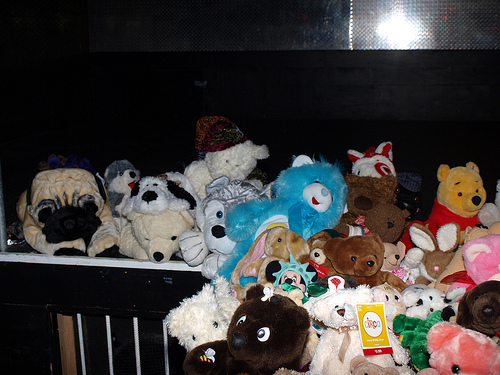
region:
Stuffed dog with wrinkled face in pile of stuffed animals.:
[15, 165, 116, 253]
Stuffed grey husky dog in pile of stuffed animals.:
[95, 156, 140, 211]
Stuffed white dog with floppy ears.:
[120, 170, 200, 215]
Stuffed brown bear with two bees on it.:
[182, 282, 308, 372]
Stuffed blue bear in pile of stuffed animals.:
[213, 153, 348, 285]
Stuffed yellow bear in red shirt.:
[425, 161, 487, 246]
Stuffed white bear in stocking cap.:
[182, 113, 267, 196]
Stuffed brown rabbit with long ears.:
[230, 225, 306, 300]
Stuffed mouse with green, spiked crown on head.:
[265, 250, 315, 285]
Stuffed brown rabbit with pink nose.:
[409, 223, 459, 286]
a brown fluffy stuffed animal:
[325, 233, 403, 290]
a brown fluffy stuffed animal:
[181, 282, 320, 370]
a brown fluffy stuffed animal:
[344, 171, 396, 215]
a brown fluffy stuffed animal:
[337, 200, 407, 245]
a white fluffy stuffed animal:
[164, 285, 238, 348]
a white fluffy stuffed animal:
[304, 285, 404, 373]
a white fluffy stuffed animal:
[374, 281, 414, 365]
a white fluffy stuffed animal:
[400, 282, 463, 320]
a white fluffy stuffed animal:
[177, 137, 267, 191]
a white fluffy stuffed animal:
[117, 206, 201, 265]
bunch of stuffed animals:
[26, 144, 490, 345]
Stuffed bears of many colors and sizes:
[298, 169, 455, 354]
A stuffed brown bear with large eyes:
[221, 288, 296, 372]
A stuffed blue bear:
[283, 162, 344, 238]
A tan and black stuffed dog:
[18, 164, 116, 247]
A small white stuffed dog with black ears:
[117, 177, 183, 217]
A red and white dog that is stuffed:
[339, 142, 401, 180]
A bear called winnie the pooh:
[429, 147, 489, 238]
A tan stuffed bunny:
[248, 220, 299, 270]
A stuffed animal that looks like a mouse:
[373, 238, 406, 276]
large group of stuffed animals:
[24, 107, 496, 364]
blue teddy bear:
[207, 155, 349, 275]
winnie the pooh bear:
[418, 155, 490, 240]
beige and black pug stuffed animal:
[10, 168, 116, 257]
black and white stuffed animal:
[343, 133, 398, 180]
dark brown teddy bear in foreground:
[177, 283, 313, 371]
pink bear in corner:
[418, 325, 490, 374]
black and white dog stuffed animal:
[112, 173, 194, 217]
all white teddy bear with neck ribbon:
[309, 284, 384, 374]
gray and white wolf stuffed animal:
[100, 161, 140, 216]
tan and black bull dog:
[34, 175, 123, 260]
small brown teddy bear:
[327, 225, 385, 278]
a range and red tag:
[352, 297, 399, 371]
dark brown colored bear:
[220, 301, 306, 373]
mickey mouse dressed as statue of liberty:
[264, 250, 324, 301]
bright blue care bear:
[260, 147, 350, 269]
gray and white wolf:
[186, 187, 257, 272]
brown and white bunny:
[404, 216, 458, 298]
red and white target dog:
[356, 147, 393, 191]